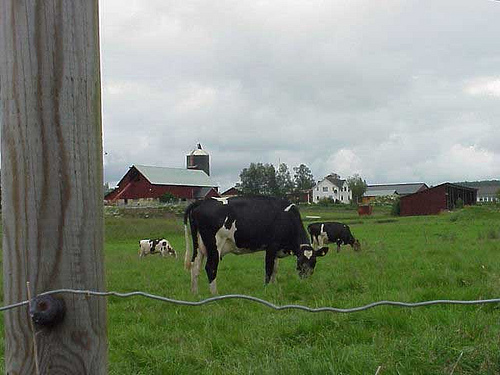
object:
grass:
[0, 203, 500, 375]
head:
[290, 245, 329, 279]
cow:
[183, 192, 330, 298]